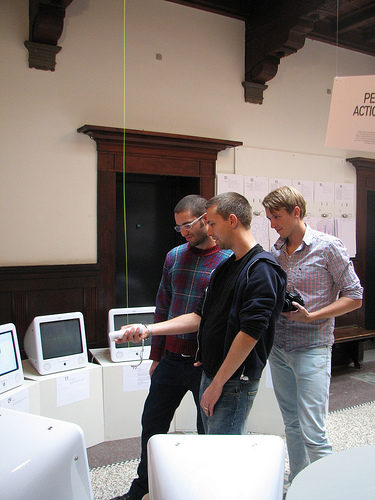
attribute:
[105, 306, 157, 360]
tv — white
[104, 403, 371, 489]
rug — white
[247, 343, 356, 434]
jeans — light blue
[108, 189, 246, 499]
man — white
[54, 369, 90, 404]
paper — white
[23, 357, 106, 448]
box — white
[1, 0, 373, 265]
wall — beige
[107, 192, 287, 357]
man — game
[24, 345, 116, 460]
table — white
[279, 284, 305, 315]
camera — black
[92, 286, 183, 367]
computer — white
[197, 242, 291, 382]
hoodie — navy, blue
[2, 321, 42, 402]
monitor — white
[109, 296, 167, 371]
monitor — back part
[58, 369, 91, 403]
paper — white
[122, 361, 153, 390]
paper — white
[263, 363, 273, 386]
paper — white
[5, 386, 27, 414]
paper — white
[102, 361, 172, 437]
box — white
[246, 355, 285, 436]
box — white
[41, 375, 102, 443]
box — white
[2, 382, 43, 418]
box — white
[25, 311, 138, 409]
monitor — white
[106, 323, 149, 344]
game controller — video